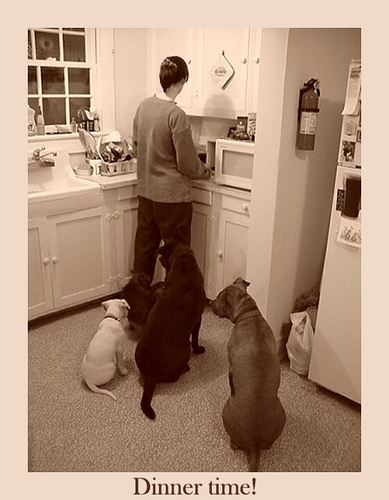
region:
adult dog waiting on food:
[206, 281, 298, 468]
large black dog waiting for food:
[135, 230, 217, 402]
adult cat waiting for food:
[117, 262, 178, 334]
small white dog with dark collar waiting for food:
[76, 289, 142, 403]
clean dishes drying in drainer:
[69, 126, 153, 181]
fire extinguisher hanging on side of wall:
[290, 75, 331, 166]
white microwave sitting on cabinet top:
[202, 131, 283, 205]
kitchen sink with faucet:
[31, 139, 107, 221]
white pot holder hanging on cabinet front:
[206, 45, 247, 98]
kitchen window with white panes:
[30, 36, 122, 148]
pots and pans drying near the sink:
[75, 115, 139, 181]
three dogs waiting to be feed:
[88, 70, 344, 451]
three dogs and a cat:
[46, 240, 306, 448]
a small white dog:
[71, 284, 143, 419]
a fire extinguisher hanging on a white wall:
[278, 68, 330, 195]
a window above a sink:
[13, 40, 115, 198]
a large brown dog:
[204, 254, 294, 477]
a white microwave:
[204, 127, 267, 196]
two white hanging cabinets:
[198, 31, 266, 118]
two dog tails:
[64, 354, 183, 420]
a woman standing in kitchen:
[118, 46, 213, 333]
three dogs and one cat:
[72, 230, 299, 472]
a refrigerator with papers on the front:
[302, 57, 363, 414]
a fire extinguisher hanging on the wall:
[290, 69, 326, 161]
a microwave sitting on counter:
[205, 131, 255, 192]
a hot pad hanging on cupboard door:
[206, 43, 249, 98]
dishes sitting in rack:
[78, 127, 137, 179]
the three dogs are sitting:
[73, 221, 294, 477]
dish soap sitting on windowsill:
[26, 100, 40, 140]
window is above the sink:
[26, 27, 100, 139]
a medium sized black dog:
[124, 204, 205, 437]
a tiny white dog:
[65, 269, 141, 418]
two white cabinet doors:
[27, 200, 110, 341]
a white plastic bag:
[282, 302, 339, 390]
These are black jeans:
[108, 158, 213, 337]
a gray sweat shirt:
[115, 84, 220, 210]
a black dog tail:
[128, 365, 162, 433]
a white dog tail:
[84, 378, 120, 400]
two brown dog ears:
[217, 263, 258, 306]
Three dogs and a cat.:
[75, 242, 288, 475]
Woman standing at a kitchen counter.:
[131, 54, 213, 281]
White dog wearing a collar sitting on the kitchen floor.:
[78, 294, 131, 402]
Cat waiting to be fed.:
[121, 267, 164, 331]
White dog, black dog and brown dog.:
[78, 232, 288, 471]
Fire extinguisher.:
[293, 75, 322, 151]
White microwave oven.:
[211, 137, 253, 192]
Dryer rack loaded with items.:
[79, 128, 139, 176]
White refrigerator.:
[307, 58, 362, 402]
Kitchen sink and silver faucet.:
[29, 143, 100, 201]